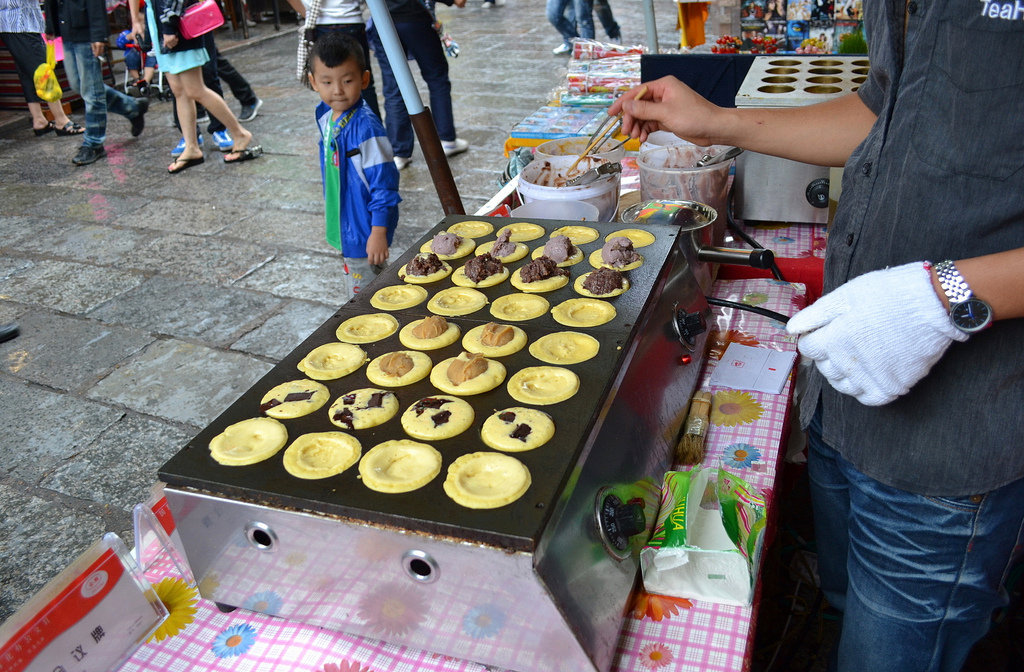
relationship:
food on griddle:
[172, 187, 667, 544] [120, 161, 786, 667]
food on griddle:
[215, 192, 646, 536] [151, 194, 746, 665]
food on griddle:
[170, 198, 683, 566] [151, 194, 746, 665]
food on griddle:
[192, 209, 666, 538] [151, 194, 746, 665]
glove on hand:
[788, 258, 966, 406] [775, 258, 957, 423]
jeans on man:
[805, 431, 1009, 667] [581, 6, 1007, 666]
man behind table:
[581, 6, 1007, 666] [75, 23, 825, 669]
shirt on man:
[781, 8, 1023, 486] [581, 6, 1007, 666]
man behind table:
[581, 6, 1007, 666] [40, 55, 844, 667]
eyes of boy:
[315, 73, 368, 99] [289, 21, 436, 300]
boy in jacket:
[289, 21, 436, 300] [304, 99, 413, 270]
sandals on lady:
[153, 144, 290, 177] [118, 1, 276, 177]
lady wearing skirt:
[118, 1, 276, 177] [142, 10, 236, 86]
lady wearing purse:
[146, 1, 259, 172] [175, 1, 249, 58]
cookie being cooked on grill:
[486, 393, 571, 473] [151, 208, 722, 666]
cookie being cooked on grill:
[395, 380, 480, 450] [144, 174, 750, 669]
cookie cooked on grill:
[362, 346, 427, 381] [189, 206, 689, 626]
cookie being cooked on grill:
[441, 448, 534, 509] [151, 208, 722, 666]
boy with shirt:
[305, 29, 412, 287] [300, 108, 380, 247]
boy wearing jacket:
[305, 29, 412, 287] [301, 103, 397, 250]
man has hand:
[609, 0, 1022, 671] [787, 253, 983, 412]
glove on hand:
[788, 258, 950, 400] [787, 253, 983, 412]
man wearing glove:
[609, 0, 1022, 671] [788, 258, 950, 400]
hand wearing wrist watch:
[788, 253, 983, 412] [925, 252, 997, 341]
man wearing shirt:
[609, 0, 1022, 671] [796, 1, 1016, 501]